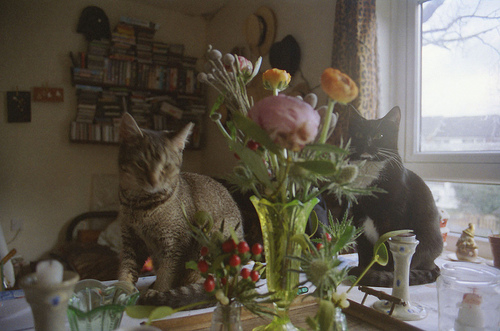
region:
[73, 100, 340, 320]
Grey Cat Vase Flowers Red berries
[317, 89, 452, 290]
Black cat White chest on cat Green Plants Candle holder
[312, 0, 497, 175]
Window Closed window Curtain Leopard print curtain tree with no leaves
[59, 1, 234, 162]
Bookshelf Clutter Books Shelf on wall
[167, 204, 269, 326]
Plant in vase vase red berries green foliage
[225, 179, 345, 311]
vase flowers in vase green vase green foliage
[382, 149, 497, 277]
Figurines Window Pot closed window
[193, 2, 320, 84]
hats hats on wall cobwebs in curtain yellow flower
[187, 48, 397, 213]
flowers yellow flowers pink flower green foliage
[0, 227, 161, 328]
candle candle holder vase table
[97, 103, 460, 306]
two cats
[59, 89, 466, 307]
two cats on table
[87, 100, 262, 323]
cat on table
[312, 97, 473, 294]
cat on table together in kitchen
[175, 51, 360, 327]
flowers in vase on table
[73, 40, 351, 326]
cat looks at vase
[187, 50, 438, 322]
cat looks at vase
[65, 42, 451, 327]
cats and flowers on table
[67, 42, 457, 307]
cats in kitchen together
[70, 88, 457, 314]
cats together in kitchen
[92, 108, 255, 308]
Cat sitting on the table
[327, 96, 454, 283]
Black and white cat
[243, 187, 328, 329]
Off colored yellow vase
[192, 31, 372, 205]
Various flowers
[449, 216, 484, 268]
Little figure in window sill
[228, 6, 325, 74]
Two hats hanging on the wall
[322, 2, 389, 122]
Cheetah print curtains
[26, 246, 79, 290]
small white candle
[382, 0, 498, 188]
Window showing outside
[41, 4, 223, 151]
Lots of books on the back wall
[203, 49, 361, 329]
vase of flowers sitting on table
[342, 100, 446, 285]
black and white cat on table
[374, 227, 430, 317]
white candlestick holder with blue dots on it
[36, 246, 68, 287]
small white candle on top of a candle holder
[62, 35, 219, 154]
Various books up on the wall shelf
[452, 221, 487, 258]
little decoration in the window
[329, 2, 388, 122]
cheetah print curtain hanging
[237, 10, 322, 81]
two hats hanging on the wall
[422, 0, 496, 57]
branches outside the window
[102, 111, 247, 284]
the brown tabby cat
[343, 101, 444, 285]
the black and white cat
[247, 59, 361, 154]
pink and orange flowers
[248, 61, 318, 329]
a green glass vase with flowers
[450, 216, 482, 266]
a figuring of a dwarf near the window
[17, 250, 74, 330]
a white candle in a candle stick holder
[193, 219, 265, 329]
bunch of red berries in a vase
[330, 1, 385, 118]
leopard print curtains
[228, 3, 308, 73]
two hats hanging on the wall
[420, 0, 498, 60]
tree branches outside the window